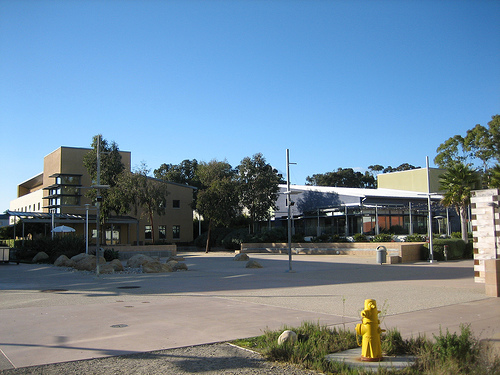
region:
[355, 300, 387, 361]
A yellow fire hydrant.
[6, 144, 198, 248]
A tall tan brick building with white area on the side.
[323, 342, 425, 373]
Concrete slab with a fire hydrant on it.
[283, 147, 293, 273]
Tall thin metal pole in the middle of a concrete drive area.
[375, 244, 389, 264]
A grey trashcan.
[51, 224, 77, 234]
A white opened umbrella.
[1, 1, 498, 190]
A blue sky.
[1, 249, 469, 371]
A large grey paved drive area.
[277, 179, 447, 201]
A pitched white large roof.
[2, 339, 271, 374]
Shadow on the ground with a long pole and diamond shaped sign.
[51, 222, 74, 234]
An open white umbrella.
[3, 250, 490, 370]
Large grey concreted drive.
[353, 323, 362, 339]
A large yellow cap on the side of a hydrant.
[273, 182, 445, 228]
A blue building with a white pitched roof.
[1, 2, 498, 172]
The blue sky.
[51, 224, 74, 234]
The top of an opened white umbrella.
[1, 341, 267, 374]
A dark shadow on the ground of a pole with a diamond shaped sign on it.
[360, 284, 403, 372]
fire hydrant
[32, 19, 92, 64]
white clouds in blue sky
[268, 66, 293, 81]
white clouds in blue sky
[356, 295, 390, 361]
Yellow fire hydrant on street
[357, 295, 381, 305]
Top of yellow fire hydrant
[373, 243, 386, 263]
Trash can on street curb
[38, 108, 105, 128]
Nice clear blue sky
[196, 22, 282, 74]
Nice clear blue sky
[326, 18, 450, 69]
Nice clear blue sky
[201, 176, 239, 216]
Part of green trees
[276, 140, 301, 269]
Pole on side of street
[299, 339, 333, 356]
Green grassy area near hydrant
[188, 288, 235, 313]
gray asphalt on road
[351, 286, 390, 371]
A yellow fire hydrant by the grass.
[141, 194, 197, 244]
The building has indows.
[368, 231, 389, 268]
A garbage can in front of building.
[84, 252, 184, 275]
Rocks on the lot.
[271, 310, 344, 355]
Green grass by fire hydrant.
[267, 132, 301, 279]
A silver pole in the empty lot.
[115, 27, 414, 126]
The sky is clear and blue.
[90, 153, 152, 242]
A tree by the building.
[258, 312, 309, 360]
A rock on the grass.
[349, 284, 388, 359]
The fire hydrant is yellow.